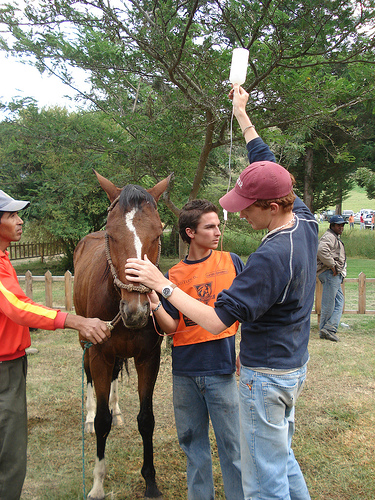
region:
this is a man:
[227, 169, 306, 484]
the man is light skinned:
[251, 210, 274, 233]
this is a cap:
[234, 163, 272, 203]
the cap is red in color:
[252, 173, 275, 202]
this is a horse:
[82, 202, 151, 397]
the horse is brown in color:
[85, 246, 104, 292]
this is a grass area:
[319, 403, 355, 489]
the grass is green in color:
[317, 435, 341, 486]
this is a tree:
[104, 24, 207, 154]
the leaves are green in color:
[52, 142, 79, 197]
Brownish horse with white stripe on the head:
[70, 166, 172, 498]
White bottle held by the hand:
[227, 45, 249, 99]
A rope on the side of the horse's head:
[103, 231, 112, 279]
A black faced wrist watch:
[160, 281, 173, 299]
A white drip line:
[225, 118, 234, 187]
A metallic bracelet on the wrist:
[240, 123, 256, 133]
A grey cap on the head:
[0, 188, 31, 211]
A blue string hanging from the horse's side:
[78, 353, 88, 488]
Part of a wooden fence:
[356, 269, 367, 316]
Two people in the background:
[347, 211, 364, 228]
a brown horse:
[67, 175, 173, 258]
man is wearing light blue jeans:
[235, 382, 293, 495]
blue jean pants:
[177, 383, 217, 498]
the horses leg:
[91, 376, 122, 490]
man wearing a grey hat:
[2, 189, 28, 208]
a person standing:
[319, 213, 351, 342]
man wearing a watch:
[157, 284, 178, 296]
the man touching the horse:
[127, 255, 162, 285]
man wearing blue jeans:
[321, 272, 346, 333]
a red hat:
[232, 160, 302, 196]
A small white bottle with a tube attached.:
[153, 46, 252, 339]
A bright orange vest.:
[164, 251, 241, 347]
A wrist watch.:
[159, 284, 178, 299]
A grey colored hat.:
[0, 191, 30, 214]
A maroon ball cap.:
[217, 160, 293, 213]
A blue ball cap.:
[329, 214, 347, 224]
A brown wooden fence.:
[0, 242, 374, 317]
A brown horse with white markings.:
[71, 169, 171, 499]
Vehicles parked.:
[319, 206, 373, 228]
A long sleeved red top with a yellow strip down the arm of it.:
[0, 252, 68, 359]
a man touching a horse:
[125, 163, 343, 328]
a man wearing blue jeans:
[238, 362, 314, 498]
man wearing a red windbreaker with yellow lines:
[0, 251, 61, 360]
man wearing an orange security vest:
[169, 249, 238, 343]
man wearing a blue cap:
[329, 213, 347, 226]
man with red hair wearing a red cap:
[219, 160, 296, 213]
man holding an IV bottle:
[148, 43, 249, 341]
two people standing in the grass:
[348, 211, 367, 234]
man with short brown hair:
[177, 198, 222, 255]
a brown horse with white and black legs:
[72, 173, 178, 498]